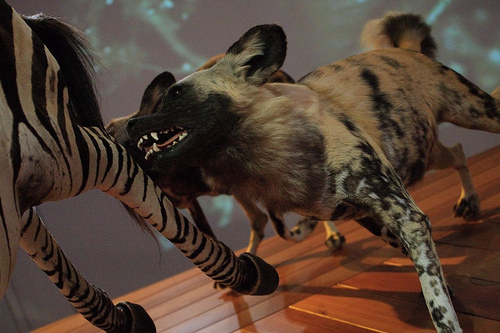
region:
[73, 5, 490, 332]
These are not real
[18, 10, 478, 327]
This is an reenactment of the wild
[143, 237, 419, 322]
The floor is made of wood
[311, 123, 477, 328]
The animal has spots on it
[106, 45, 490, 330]
This is a hyena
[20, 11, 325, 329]
The hyena is biting a zebra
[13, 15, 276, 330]
Zebra is running away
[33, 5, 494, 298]
There are lights on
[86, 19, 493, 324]
Two animals are predators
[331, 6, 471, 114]
Animal's tail is curled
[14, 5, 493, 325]
artificial hyena biting zebra leg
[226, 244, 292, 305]
hoof of a zebra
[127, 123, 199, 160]
mouth of a hyena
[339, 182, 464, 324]
leg of a hyena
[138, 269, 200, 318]
wooden table where animals are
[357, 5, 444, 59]
tail of a hyena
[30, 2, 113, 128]
tail of a zebra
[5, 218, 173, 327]
leg of a zebra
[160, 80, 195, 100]
eye of a hyena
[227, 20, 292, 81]
ear of a hyena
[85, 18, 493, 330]
a hyiena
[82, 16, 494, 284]
a hiena chasing a zebra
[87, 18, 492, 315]
a hyena going to bite zebra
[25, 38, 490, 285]
a hyena attacking zebra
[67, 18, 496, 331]
a hyena and zebra on display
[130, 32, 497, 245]
a hyena in attack mode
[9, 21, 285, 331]
a zebra running from hyena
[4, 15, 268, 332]
a black and white zebra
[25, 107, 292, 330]
two zebra's back legs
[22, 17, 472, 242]
black and white zebra with hyena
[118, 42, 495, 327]
Hyena is yellow and black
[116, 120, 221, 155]
Muzzle is black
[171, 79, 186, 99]
Eyes are small and round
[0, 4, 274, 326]
Zebra is white and black striped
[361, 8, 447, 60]
Tail of hyena is short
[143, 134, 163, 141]
Tooth is pointed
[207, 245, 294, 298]
Front left hoof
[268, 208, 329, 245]
Leg is lifted above ground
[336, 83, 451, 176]
Hyena's belly is round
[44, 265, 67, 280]
Black stripe on leg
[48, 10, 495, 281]
a hyena on display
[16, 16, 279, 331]
a zebra on display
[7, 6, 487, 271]
a zebra and hyena on display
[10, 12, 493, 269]
a hyena running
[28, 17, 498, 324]
a hyena biting zebra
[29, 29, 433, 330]
a hyena running after zebra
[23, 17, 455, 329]
zebra and hyena